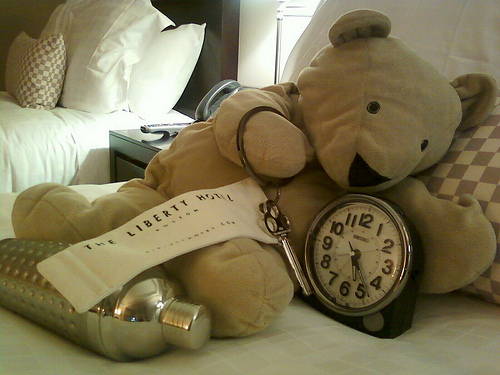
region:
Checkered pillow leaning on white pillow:
[4, 28, 67, 110]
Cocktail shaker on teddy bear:
[0, 237, 210, 359]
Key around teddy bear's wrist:
[236, 98, 311, 295]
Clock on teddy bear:
[304, 190, 417, 340]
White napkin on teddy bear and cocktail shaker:
[36, 175, 278, 313]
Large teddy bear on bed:
[9, 12, 499, 341]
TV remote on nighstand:
[134, 120, 190, 137]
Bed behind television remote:
[195, 75, 258, 120]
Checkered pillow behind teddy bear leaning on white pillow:
[421, 89, 498, 302]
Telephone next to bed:
[193, 72, 256, 122]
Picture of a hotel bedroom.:
[3, 5, 495, 373]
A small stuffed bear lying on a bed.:
[20, 10, 481, 321]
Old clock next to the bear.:
[302, 190, 423, 345]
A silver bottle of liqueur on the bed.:
[0, 230, 215, 365]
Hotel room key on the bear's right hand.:
[36, 161, 306, 321]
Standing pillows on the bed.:
[2, 5, 207, 115]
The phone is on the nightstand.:
[187, 75, 242, 125]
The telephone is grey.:
[190, 75, 240, 117]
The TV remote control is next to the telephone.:
[140, 115, 192, 135]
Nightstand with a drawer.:
[105, 147, 161, 177]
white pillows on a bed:
[39, 0, 209, 113]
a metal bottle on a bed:
[1, 233, 210, 362]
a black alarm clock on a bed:
[300, 188, 423, 336]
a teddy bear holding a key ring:
[233, 104, 315, 301]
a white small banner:
[37, 172, 283, 315]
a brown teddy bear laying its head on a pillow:
[15, 9, 497, 332]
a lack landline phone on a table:
[194, 70, 259, 127]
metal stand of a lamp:
[271, 4, 287, 83]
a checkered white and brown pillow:
[4, 30, 67, 109]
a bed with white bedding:
[0, 84, 196, 185]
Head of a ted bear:
[295, 0, 470, 184]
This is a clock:
[303, 187, 431, 342]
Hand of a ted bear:
[206, 80, 323, 182]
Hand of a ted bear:
[389, 175, 499, 288]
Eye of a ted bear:
[349, 90, 393, 129]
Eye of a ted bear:
[411, 129, 441, 175]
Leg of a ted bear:
[160, 176, 296, 346]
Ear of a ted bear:
[323, 0, 405, 49]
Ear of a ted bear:
[446, 50, 499, 144]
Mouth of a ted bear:
[340, 146, 402, 194]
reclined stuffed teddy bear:
[29, 16, 487, 320]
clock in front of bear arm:
[305, 191, 430, 336]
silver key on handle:
[239, 108, 316, 300]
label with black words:
[44, 181, 267, 307]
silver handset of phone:
[192, 79, 245, 123]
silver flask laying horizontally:
[2, 235, 211, 361]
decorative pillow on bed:
[21, 30, 64, 107]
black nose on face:
[339, 153, 396, 193]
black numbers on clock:
[311, 210, 396, 301]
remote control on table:
[140, 120, 196, 138]